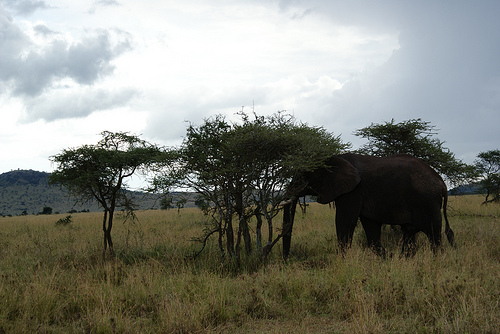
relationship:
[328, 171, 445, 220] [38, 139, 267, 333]
elephant on plains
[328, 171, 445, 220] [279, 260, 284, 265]
elephant looking for food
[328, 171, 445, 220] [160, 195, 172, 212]
elephant near shrub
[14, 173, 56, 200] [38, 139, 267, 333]
hill on plains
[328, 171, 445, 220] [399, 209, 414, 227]
elephant walking alone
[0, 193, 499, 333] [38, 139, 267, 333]
grass on plains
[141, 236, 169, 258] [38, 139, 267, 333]
grass on plains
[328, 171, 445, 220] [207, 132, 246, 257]
elephant next to tree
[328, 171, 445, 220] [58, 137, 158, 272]
elephant next to tree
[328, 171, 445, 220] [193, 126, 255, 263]
elephant next to tree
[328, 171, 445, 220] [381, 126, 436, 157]
elephant next to tree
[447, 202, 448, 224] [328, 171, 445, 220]
tail on elephant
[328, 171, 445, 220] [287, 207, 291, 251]
elephant has trunk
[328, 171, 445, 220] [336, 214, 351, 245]
elephant has leg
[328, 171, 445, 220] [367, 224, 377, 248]
elephant has leg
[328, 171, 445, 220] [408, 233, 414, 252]
elephant has leg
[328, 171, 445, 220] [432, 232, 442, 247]
elephant has leg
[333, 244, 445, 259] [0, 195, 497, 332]
feet in grass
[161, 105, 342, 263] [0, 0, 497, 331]
tree in africa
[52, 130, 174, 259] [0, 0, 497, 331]
tree in africa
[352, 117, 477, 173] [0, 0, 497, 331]
tree in africa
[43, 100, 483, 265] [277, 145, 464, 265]
bushes next to elephant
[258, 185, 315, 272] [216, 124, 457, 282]
trunk of elephant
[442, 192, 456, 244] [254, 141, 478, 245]
tail of elephant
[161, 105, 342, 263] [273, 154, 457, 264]
tree near elephant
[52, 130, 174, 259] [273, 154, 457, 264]
tree near elephant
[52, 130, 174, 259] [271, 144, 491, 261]
tree behind elephant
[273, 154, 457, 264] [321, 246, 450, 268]
elephant standing in grass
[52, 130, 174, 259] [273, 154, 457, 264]
tree over elephant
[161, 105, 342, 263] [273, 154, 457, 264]
tree over elephant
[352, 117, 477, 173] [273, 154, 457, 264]
tree over elephant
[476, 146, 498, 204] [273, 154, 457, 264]
tree over elephant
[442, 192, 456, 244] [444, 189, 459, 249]
tail of elephant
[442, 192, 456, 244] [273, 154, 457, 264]
tail of elephant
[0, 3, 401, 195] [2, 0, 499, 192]
bad clouds in sky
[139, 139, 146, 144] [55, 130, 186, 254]
leaf on tree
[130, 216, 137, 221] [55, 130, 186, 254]
leaf on tree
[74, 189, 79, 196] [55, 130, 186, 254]
leaf on tree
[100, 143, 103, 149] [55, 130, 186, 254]
leaf on tree